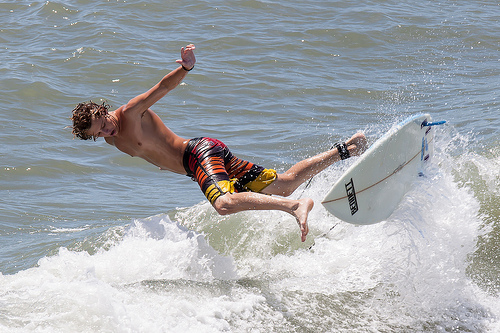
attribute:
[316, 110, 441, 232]
surfboard — Underside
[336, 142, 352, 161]
ankle — man's 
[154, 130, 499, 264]
wave — crashes,  splashing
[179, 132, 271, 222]
trunks — Colorful 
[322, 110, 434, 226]
white surfboard — White 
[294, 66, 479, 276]
surfboard — white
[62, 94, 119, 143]
hair — curly , wet 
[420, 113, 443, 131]
fin — Blue